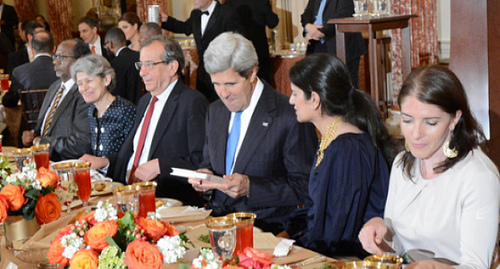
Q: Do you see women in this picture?
A: Yes, there is a woman.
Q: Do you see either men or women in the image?
A: Yes, there is a woman.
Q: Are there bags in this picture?
A: No, there are no bags.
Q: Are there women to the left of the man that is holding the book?
A: Yes, there is a woman to the left of the man.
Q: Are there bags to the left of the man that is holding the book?
A: No, there is a woman to the left of the man.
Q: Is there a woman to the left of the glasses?
A: Yes, there is a woman to the left of the glasses.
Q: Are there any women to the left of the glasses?
A: Yes, there is a woman to the left of the glasses.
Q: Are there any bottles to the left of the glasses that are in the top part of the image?
A: No, there is a woman to the left of the glasses.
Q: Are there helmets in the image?
A: No, there are no helmets.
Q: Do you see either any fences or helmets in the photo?
A: No, there are no helmets or fences.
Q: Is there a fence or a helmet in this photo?
A: No, there are no helmets or fences.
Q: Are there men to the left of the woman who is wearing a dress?
A: Yes, there is a man to the left of the woman.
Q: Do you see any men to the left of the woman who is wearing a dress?
A: Yes, there is a man to the left of the woman.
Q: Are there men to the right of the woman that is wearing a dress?
A: No, the man is to the left of the woman.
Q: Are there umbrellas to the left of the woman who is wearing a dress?
A: No, there is a man to the left of the woman.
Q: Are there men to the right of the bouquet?
A: Yes, there is a man to the right of the bouquet.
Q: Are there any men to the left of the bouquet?
A: No, the man is to the right of the bouquet.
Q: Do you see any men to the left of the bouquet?
A: No, the man is to the right of the bouquet.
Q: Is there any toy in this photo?
A: No, there are no toys.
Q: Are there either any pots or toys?
A: No, there are no toys or pots.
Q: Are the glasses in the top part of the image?
A: Yes, the glasses are in the top of the image.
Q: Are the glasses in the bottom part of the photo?
A: No, the glasses are in the top of the image.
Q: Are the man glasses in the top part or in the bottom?
A: The glasses are in the top of the image.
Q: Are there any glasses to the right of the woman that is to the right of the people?
A: Yes, there are glasses to the right of the woman.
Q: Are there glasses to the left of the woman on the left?
A: No, the glasses are to the right of the woman.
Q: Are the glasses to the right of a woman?
A: Yes, the glasses are to the right of a woman.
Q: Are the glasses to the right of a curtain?
A: No, the glasses are to the right of a woman.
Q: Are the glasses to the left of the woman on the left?
A: No, the glasses are to the right of the woman.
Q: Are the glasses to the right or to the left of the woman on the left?
A: The glasses are to the right of the woman.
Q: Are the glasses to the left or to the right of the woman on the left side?
A: The glasses are to the right of the woman.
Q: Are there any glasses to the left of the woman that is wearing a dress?
A: Yes, there are glasses to the left of the woman.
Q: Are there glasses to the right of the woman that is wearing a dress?
A: No, the glasses are to the left of the woman.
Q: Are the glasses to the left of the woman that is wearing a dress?
A: Yes, the glasses are to the left of the woman.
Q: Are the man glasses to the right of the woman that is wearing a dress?
A: No, the glasses are to the left of the woman.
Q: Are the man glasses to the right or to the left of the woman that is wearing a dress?
A: The glasses are to the left of the woman.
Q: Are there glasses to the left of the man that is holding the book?
A: Yes, there are glasses to the left of the man.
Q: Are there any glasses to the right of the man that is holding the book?
A: No, the glasses are to the left of the man.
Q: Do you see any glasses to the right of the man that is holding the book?
A: No, the glasses are to the left of the man.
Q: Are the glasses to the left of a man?
A: Yes, the glasses are to the left of a man.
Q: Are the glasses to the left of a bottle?
A: No, the glasses are to the left of a man.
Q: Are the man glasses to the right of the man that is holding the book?
A: No, the glasses are to the left of the man.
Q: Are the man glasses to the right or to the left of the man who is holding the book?
A: The glasses are to the left of the man.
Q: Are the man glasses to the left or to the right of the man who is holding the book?
A: The glasses are to the left of the man.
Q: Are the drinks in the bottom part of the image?
A: Yes, the drinks are in the bottom of the image.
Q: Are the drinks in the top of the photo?
A: No, the drinks are in the bottom of the image.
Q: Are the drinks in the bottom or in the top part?
A: The drinks are in the bottom of the image.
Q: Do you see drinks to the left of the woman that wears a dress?
A: Yes, there are drinks to the left of the woman.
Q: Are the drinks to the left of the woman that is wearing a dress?
A: Yes, the drinks are to the left of the woman.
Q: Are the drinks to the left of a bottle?
A: No, the drinks are to the left of the woman.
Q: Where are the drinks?
A: The drinks are at the dinner.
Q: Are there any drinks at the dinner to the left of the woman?
A: Yes, there are drinks at the dinner.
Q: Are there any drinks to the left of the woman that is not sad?
A: Yes, there are drinks to the left of the woman.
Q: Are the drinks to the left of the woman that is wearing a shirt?
A: Yes, the drinks are to the left of the woman.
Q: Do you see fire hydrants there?
A: No, there are no fire hydrants.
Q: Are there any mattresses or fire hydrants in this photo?
A: No, there are no fire hydrants or mattresses.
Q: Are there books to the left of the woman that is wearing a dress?
A: Yes, there is a book to the left of the woman.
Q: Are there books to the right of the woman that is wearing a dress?
A: No, the book is to the left of the woman.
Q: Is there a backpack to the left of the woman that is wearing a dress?
A: No, there is a book to the left of the woman.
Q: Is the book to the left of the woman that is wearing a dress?
A: Yes, the book is to the left of the woman.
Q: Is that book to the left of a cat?
A: No, the book is to the left of the woman.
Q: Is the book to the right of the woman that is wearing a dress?
A: No, the book is to the left of the woman.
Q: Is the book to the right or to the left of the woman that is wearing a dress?
A: The book is to the left of the woman.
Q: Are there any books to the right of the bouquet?
A: Yes, there is a book to the right of the bouquet.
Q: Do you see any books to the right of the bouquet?
A: Yes, there is a book to the right of the bouquet.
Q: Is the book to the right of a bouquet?
A: Yes, the book is to the right of a bouquet.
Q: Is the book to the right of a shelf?
A: No, the book is to the right of a bouquet.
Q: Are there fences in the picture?
A: No, there are no fences.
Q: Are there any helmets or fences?
A: No, there are no fences or helmets.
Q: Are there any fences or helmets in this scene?
A: No, there are no fences or helmets.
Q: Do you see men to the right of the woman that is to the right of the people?
A: Yes, there is a man to the right of the woman.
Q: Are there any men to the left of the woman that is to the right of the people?
A: No, the man is to the right of the woman.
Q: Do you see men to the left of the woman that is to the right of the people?
A: No, the man is to the right of the woman.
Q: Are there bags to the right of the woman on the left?
A: No, there is a man to the right of the woman.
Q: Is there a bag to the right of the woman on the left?
A: No, there is a man to the right of the woman.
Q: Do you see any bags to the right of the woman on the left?
A: No, there is a man to the right of the woman.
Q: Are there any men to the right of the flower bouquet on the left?
A: Yes, there is a man to the right of the flower bouquet.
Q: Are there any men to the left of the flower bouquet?
A: No, the man is to the right of the flower bouquet.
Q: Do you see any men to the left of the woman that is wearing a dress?
A: Yes, there is a man to the left of the woman.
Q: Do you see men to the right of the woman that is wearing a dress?
A: No, the man is to the left of the woman.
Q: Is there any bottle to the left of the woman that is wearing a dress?
A: No, there is a man to the left of the woman.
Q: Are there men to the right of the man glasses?
A: Yes, there is a man to the right of the glasses.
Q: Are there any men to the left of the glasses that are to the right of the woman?
A: No, the man is to the right of the glasses.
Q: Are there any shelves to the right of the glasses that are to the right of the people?
A: No, there is a man to the right of the glasses.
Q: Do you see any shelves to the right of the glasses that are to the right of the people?
A: No, there is a man to the right of the glasses.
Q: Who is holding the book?
A: The man is holding the book.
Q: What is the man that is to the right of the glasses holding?
A: The man is holding the book.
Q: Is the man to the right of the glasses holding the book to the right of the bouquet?
A: Yes, the man is holding the book.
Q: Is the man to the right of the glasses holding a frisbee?
A: No, the man is holding the book.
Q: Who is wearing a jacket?
A: The man is wearing a jacket.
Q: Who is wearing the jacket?
A: The man is wearing a jacket.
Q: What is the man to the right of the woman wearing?
A: The man is wearing a jacket.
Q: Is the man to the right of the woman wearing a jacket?
A: Yes, the man is wearing a jacket.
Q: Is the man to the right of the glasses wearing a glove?
A: No, the man is wearing a jacket.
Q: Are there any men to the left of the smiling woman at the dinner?
A: Yes, there is a man to the left of the woman.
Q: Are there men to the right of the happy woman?
A: No, the man is to the left of the woman.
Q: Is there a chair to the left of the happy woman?
A: No, there is a man to the left of the woman.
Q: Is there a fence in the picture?
A: No, there are no fences.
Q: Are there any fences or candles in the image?
A: No, there are no fences or candles.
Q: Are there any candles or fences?
A: No, there are no fences or candles.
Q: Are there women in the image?
A: Yes, there is a woman.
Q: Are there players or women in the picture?
A: Yes, there is a woman.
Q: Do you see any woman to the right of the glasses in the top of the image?
A: Yes, there is a woman to the right of the glasses.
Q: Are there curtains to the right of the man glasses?
A: No, there is a woman to the right of the glasses.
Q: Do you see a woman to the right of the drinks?
A: Yes, there is a woman to the right of the drinks.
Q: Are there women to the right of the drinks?
A: Yes, there is a woman to the right of the drinks.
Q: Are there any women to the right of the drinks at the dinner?
A: Yes, there is a woman to the right of the drinks.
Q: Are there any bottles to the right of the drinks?
A: No, there is a woman to the right of the drinks.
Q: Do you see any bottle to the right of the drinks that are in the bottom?
A: No, there is a woman to the right of the drinks.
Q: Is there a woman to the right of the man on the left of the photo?
A: Yes, there is a woman to the right of the man.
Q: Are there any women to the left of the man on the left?
A: No, the woman is to the right of the man.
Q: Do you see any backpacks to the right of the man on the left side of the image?
A: No, there is a woman to the right of the man.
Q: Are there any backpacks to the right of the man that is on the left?
A: No, there is a woman to the right of the man.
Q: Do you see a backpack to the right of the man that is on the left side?
A: No, there is a woman to the right of the man.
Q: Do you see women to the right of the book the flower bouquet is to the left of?
A: Yes, there is a woman to the right of the book.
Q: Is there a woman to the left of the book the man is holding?
A: No, the woman is to the right of the book.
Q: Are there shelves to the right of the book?
A: No, there is a woman to the right of the book.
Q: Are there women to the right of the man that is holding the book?
A: Yes, there is a woman to the right of the man.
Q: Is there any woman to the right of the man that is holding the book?
A: Yes, there is a woman to the right of the man.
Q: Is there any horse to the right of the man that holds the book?
A: No, there is a woman to the right of the man.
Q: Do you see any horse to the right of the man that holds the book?
A: No, there is a woman to the right of the man.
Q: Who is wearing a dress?
A: The woman is wearing a dress.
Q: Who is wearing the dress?
A: The woman is wearing a dress.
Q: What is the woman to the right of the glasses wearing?
A: The woman is wearing a dress.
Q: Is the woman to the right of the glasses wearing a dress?
A: Yes, the woman is wearing a dress.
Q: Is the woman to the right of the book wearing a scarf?
A: No, the woman is wearing a dress.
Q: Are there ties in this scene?
A: Yes, there is a tie.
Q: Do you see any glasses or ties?
A: Yes, there is a tie.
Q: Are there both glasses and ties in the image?
A: Yes, there are both a tie and glasses.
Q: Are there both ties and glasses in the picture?
A: Yes, there are both a tie and glasses.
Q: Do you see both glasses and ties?
A: Yes, there are both a tie and glasses.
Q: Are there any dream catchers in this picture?
A: No, there are no dream catchers.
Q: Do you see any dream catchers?
A: No, there are no dream catchers.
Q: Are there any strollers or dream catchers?
A: No, there are no dream catchers or strollers.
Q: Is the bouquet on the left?
A: Yes, the bouquet is on the left of the image.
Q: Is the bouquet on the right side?
A: No, the bouquet is on the left of the image.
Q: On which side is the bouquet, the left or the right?
A: The bouquet is on the left of the image.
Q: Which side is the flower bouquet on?
A: The flower bouquet is on the left of the image.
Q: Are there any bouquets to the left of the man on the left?
A: Yes, there is a bouquet to the left of the man.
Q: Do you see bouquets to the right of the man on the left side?
A: No, the bouquet is to the left of the man.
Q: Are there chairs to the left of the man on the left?
A: No, there is a bouquet to the left of the man.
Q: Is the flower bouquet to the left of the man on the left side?
A: Yes, the flower bouquet is to the left of the man.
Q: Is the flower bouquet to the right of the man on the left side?
A: No, the flower bouquet is to the left of the man.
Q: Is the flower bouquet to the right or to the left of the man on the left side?
A: The flower bouquet is to the left of the man.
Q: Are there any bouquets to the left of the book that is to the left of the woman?
A: Yes, there is a bouquet to the left of the book.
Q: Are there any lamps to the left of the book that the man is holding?
A: No, there is a bouquet to the left of the book.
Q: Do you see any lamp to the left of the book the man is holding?
A: No, there is a bouquet to the left of the book.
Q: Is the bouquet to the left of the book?
A: Yes, the bouquet is to the left of the book.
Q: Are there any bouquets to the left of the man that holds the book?
A: Yes, there is a bouquet to the left of the man.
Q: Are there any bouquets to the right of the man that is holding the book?
A: No, the bouquet is to the left of the man.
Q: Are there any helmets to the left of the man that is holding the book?
A: No, there is a bouquet to the left of the man.